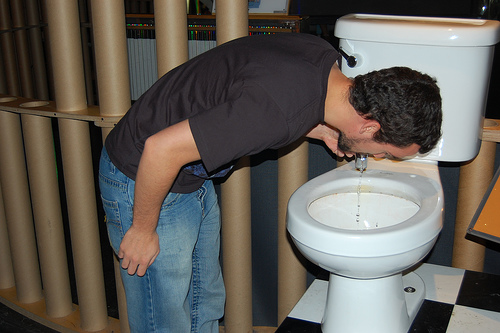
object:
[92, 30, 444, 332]
man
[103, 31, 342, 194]
t-shirt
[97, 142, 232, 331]
jeans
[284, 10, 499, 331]
toilet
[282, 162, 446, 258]
toilet bowl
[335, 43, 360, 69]
handle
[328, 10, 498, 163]
toilet tank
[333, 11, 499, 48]
top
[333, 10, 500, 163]
tank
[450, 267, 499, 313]
tiles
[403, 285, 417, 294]
bolt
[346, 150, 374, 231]
liquid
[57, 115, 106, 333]
tubing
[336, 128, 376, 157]
beard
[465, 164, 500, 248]
sign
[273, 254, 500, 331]
platform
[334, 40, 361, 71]
lever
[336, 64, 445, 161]
head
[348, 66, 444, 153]
hair